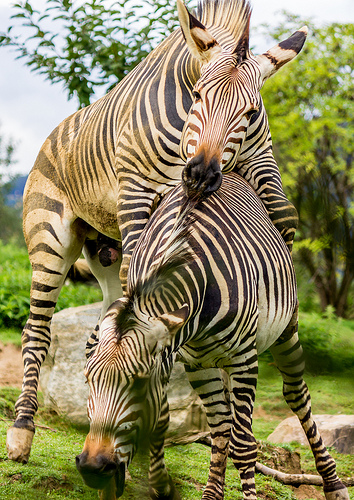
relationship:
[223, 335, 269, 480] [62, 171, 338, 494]
leg of zebra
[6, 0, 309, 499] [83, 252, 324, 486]
animal on top of zebra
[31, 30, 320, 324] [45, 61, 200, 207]
animal with stripes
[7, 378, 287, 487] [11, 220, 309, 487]
grass on ground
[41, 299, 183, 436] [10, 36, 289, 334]
rock behind zebra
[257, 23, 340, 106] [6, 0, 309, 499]
ear on animal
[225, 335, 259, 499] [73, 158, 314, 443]
leg on zebra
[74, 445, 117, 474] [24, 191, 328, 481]
nose on zebra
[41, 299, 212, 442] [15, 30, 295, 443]
rock behind zebras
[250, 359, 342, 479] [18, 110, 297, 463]
rock behind zebras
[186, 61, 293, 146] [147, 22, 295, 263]
eyes on face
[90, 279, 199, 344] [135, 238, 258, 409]
mane on neck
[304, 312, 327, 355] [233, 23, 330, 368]
leaves on tree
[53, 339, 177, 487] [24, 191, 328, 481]
head of zebra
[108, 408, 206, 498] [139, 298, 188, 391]
nose has fur